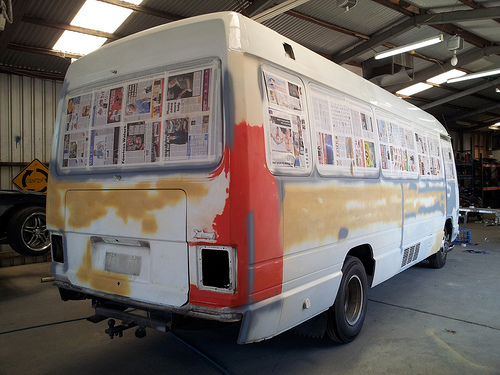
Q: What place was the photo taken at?
A: It was taken at the road.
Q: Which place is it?
A: It is a road.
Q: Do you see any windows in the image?
A: Yes, there is a window.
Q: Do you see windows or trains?
A: Yes, there is a window.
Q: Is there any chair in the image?
A: No, there are no chairs.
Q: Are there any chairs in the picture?
A: No, there are no chairs.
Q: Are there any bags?
A: No, there are no bags.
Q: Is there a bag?
A: No, there are no bags.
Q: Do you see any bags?
A: No, there are no bags.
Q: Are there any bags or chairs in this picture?
A: No, there are no bags or chairs.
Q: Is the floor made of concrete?
A: Yes, the floor is made of concrete.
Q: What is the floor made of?
A: The floor is made of concrete.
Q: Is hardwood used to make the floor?
A: No, the floor is made of cement.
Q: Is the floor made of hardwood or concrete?
A: The floor is made of concrete.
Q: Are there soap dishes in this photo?
A: No, there are no soap dishes.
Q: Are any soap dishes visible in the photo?
A: No, there are no soap dishes.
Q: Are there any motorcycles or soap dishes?
A: No, there are no soap dishes or motorcycles.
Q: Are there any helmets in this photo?
A: No, there are no helmets.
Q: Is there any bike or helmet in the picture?
A: No, there are no helmets or bikes.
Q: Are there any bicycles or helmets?
A: No, there are no helmets or bicycles.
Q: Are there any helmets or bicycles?
A: No, there are no helmets or bicycles.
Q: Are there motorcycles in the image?
A: No, there are no motorcycles.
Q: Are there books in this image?
A: No, there are no books.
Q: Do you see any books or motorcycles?
A: No, there are no books or motorcycles.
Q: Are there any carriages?
A: No, there are no carriages.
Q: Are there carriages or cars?
A: No, there are no carriages or cars.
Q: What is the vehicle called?
A: The vehicle is a van.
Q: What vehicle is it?
A: The vehicle is a van.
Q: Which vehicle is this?
A: This is a van.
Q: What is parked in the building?
A: The van is parked in the building.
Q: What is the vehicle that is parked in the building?
A: The vehicle is a van.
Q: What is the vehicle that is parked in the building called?
A: The vehicle is a van.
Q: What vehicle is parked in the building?
A: The vehicle is a van.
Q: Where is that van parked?
A: The van is parked in the building.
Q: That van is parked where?
A: The van is parked in the building.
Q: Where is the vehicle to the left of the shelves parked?
A: The van is parked in the building.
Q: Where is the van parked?
A: The van is parked in the building.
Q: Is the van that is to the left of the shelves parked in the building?
A: Yes, the van is parked in the building.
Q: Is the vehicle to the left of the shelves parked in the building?
A: Yes, the van is parked in the building.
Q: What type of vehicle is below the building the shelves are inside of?
A: The vehicle is a van.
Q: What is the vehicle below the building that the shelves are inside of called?
A: The vehicle is a van.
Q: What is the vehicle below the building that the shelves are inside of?
A: The vehicle is a van.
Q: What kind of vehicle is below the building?
A: The vehicle is a van.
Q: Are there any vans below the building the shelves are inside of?
A: Yes, there is a van below the building.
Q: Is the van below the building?
A: Yes, the van is below the building.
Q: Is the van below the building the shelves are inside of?
A: Yes, the van is below the building.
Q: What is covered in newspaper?
A: The van is covered in newspaper.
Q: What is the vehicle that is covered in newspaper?
A: The vehicle is a van.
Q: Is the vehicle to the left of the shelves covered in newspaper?
A: Yes, the van is covered in newspaper.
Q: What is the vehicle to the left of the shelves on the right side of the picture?
A: The vehicle is a van.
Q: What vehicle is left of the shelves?
A: The vehicle is a van.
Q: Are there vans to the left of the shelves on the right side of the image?
A: Yes, there is a van to the left of the shelves.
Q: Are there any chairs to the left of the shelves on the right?
A: No, there is a van to the left of the shelves.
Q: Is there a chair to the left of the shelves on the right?
A: No, there is a van to the left of the shelves.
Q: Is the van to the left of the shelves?
A: Yes, the van is to the left of the shelves.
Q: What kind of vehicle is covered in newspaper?
A: The vehicle is a van.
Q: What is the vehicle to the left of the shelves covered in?
A: The van is covered in newspaper.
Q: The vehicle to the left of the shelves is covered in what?
A: The van is covered in newspaper.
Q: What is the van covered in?
A: The van is covered in newspaper.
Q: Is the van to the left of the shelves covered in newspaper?
A: Yes, the van is covered in newspaper.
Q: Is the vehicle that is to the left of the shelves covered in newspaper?
A: Yes, the van is covered in newspaper.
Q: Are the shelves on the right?
A: Yes, the shelves are on the right of the image.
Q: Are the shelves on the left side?
A: No, the shelves are on the right of the image.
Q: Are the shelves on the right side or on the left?
A: The shelves are on the right of the image.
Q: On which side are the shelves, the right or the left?
A: The shelves are on the right of the image.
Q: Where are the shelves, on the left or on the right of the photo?
A: The shelves are on the right of the image.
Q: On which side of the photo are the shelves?
A: The shelves are on the right of the image.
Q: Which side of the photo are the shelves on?
A: The shelves are on the right of the image.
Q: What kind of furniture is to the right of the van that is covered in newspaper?
A: The pieces of furniture are shelves.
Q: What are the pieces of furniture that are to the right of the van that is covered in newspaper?
A: The pieces of furniture are shelves.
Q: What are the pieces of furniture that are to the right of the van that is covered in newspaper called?
A: The pieces of furniture are shelves.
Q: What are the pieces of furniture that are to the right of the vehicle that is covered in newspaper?
A: The pieces of furniture are shelves.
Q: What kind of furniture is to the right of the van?
A: The pieces of furniture are shelves.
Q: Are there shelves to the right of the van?
A: Yes, there are shelves to the right of the van.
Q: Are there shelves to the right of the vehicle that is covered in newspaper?
A: Yes, there are shelves to the right of the van.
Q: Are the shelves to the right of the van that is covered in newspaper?
A: Yes, the shelves are to the right of the van.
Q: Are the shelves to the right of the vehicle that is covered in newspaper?
A: Yes, the shelves are to the right of the van.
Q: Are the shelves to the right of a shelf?
A: No, the shelves are to the right of the van.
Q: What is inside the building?
A: The shelves are inside the building.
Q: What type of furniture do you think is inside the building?
A: The pieces of furniture are shelves.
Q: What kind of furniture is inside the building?
A: The pieces of furniture are shelves.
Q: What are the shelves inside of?
A: The shelves are inside the building.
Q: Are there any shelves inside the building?
A: Yes, there are shelves inside the building.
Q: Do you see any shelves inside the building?
A: Yes, there are shelves inside the building.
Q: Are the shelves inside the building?
A: Yes, the shelves are inside the building.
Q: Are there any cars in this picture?
A: No, there are no cars.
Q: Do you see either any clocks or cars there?
A: No, there are no cars or clocks.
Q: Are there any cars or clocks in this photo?
A: No, there are no cars or clocks.